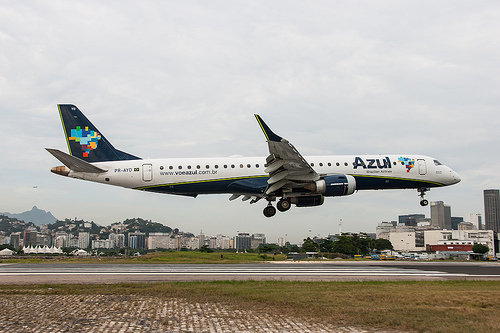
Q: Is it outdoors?
A: Yes, it is outdoors.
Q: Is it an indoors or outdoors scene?
A: It is outdoors.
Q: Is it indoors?
A: No, it is outdoors.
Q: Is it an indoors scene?
A: No, it is outdoors.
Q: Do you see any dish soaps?
A: No, there are no dish soaps.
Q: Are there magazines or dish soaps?
A: No, there are no dish soaps or magazines.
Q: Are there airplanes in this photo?
A: Yes, there is an airplane.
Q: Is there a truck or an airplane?
A: Yes, there is an airplane.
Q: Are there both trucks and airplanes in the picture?
A: No, there is an airplane but no trucks.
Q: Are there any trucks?
A: No, there are no trucks.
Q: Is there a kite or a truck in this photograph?
A: No, there are no trucks or kites.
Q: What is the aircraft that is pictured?
A: The aircraft is an airplane.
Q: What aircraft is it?
A: The aircraft is an airplane.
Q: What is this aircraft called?
A: That is an airplane.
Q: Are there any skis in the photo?
A: No, there are no skis.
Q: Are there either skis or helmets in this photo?
A: No, there are no skis or helmets.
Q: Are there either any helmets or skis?
A: No, there are no skis or helmets.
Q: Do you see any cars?
A: No, there are no cars.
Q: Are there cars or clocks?
A: No, there are no cars or clocks.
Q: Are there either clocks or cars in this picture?
A: No, there are no cars or clocks.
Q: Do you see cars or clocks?
A: No, there are no cars or clocks.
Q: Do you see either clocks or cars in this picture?
A: No, there are no cars or clocks.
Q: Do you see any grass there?
A: Yes, there is grass.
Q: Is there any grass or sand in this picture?
A: Yes, there is grass.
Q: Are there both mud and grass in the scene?
A: No, there is grass but no mud.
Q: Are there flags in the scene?
A: No, there are no flags.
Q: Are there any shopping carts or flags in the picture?
A: No, there are no flags or shopping carts.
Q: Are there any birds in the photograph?
A: No, there are no birds.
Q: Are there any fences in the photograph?
A: No, there are no fences.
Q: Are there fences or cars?
A: No, there are no fences or cars.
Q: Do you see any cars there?
A: No, there are no cars.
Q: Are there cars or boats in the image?
A: No, there are no cars or boats.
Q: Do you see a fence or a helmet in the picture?
A: No, there are no fences or helmets.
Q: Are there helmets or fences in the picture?
A: No, there are no fences or helmets.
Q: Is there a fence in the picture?
A: No, there are no fences.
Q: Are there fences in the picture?
A: No, there are no fences.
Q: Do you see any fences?
A: No, there are no fences.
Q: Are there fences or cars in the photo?
A: No, there are no fences or cars.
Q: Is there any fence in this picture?
A: No, there are no fences.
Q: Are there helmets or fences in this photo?
A: No, there are no fences or helmets.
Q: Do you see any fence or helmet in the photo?
A: No, there are no fences or helmets.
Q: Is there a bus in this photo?
A: No, there are no buses.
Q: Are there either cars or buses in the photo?
A: No, there are no buses or cars.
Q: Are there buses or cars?
A: No, there are no buses or cars.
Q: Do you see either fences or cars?
A: No, there are no fences or cars.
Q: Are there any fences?
A: No, there are no fences.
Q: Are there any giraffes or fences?
A: No, there are no fences or giraffes.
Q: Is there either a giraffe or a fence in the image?
A: No, there are no fences or giraffes.